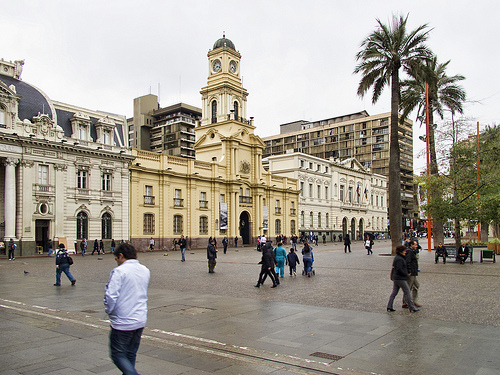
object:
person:
[101, 243, 153, 375]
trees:
[350, 8, 440, 259]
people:
[434, 241, 446, 265]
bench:
[434, 245, 474, 265]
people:
[252, 241, 277, 288]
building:
[128, 30, 302, 254]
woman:
[301, 242, 313, 278]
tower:
[192, 30, 267, 168]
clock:
[210, 58, 222, 75]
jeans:
[106, 323, 143, 374]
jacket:
[259, 241, 276, 270]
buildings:
[0, 57, 139, 259]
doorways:
[238, 209, 253, 246]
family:
[272, 241, 314, 278]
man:
[402, 240, 424, 309]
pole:
[423, 80, 431, 252]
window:
[173, 188, 184, 207]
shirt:
[102, 258, 151, 331]